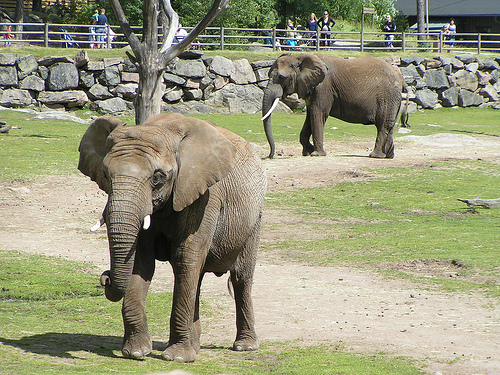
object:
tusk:
[259, 94, 281, 122]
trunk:
[104, 179, 144, 302]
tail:
[402, 86, 413, 130]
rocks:
[2, 47, 136, 118]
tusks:
[87, 216, 155, 235]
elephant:
[79, 114, 267, 363]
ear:
[174, 114, 235, 213]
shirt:
[95, 13, 111, 27]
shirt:
[318, 17, 337, 29]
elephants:
[77, 51, 410, 363]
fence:
[0, 21, 499, 56]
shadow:
[2, 332, 170, 364]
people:
[262, 9, 338, 51]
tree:
[105, 1, 226, 126]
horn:
[143, 213, 153, 230]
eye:
[101, 170, 109, 183]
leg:
[119, 245, 157, 360]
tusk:
[90, 214, 109, 233]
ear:
[75, 117, 119, 191]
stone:
[205, 54, 232, 81]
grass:
[2, 248, 430, 374]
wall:
[0, 49, 499, 114]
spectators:
[85, 6, 116, 47]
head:
[77, 116, 233, 302]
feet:
[112, 331, 262, 364]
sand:
[6, 235, 499, 369]